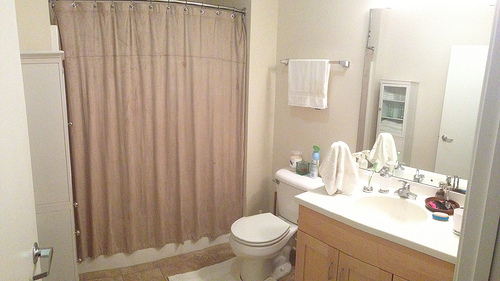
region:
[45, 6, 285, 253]
Shower curtain stretched across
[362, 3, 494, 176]
Mirror on the wall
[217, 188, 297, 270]
Toilet sitting on the floor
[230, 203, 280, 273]
The toilet is closed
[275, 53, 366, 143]
Towel hanging on a rack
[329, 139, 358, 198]
Towel sitting on sink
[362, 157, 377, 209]
tooth brush in a cup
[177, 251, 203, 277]
mat underneath the toilet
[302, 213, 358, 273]
Cabinet under the sink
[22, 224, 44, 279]
Silver door knob on the door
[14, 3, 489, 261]
a mid-sized bathroom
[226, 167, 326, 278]
a toilet in a bathroom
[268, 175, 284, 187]
the handle on a toilet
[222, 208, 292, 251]
the seat on a toilet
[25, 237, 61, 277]
a silver handle on a bathroom door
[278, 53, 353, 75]
a wash towel holder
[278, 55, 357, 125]
a wash towel in a bathroom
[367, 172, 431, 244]
a bathroom sing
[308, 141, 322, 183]
a can of air freshener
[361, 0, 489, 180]
a large mirror in a bathrooom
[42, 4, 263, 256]
Brownish tan shower curtain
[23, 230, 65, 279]
Silver door handle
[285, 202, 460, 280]
Brown wooden bathroom cabinet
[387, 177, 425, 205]
Stainless steel sink faucet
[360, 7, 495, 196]
Bath room mirror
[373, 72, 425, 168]
reflection of bathroom storage cabinet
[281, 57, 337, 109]
White towel hanging on rack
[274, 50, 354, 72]
Silver bathroom towel rack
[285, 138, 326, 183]
Bottles on back of toilet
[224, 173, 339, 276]
White bathroom toilet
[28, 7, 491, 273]
white and tan bathroom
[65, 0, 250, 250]
shower curtain pulled across opening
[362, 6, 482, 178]
mirror reflecting cabinet and door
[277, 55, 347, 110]
white towel hanging from rod on wall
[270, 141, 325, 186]
bottles and containers on toilet tank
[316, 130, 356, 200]
towel draped over object on counter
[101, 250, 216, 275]
tan hues on tiled floor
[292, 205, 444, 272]
wooden vanity under white counter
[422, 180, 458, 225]
cup and flat containers on side of sink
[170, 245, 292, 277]
white mat surrounding base of toilet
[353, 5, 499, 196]
Bathroom mirror above sink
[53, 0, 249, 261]
Beige shower curtains hung on metal bar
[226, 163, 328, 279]
White porcelain toilet with the lid down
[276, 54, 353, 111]
White towel hung on metal railing on the wall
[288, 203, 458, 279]
Wooden cupboard under the sink with double doors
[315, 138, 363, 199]
Object covered with a small white towel on the sink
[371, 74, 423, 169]
Reflection of white medicine cabinet in bathroom mirror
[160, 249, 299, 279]
White rug around toilet on the floor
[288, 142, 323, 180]
Toiletries on top of toilet tank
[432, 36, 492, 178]
White door reflected on bathroom mirror